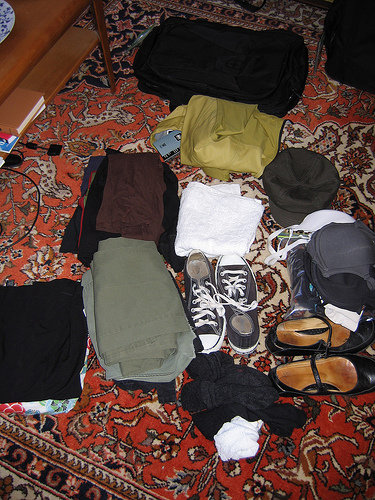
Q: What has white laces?
A: Sneakers.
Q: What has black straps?
A: Shoes.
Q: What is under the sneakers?
A: Rug.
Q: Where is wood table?
A: Left side.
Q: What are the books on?
A: Table shelf.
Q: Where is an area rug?
A: On the floor.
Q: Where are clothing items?
A: On the rug.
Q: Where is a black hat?
A: On the rug.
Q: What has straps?
A: Black shoes.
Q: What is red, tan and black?
A: The rug.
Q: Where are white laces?
A: On black and white sneakers.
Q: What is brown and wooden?
A: The floor.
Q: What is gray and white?
A: Sneakers.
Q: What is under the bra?
A: Mary janes.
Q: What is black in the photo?
A: Luggage.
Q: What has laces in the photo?
A: Shoes.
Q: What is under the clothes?
A: A rug.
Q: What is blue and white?
A: The sneakers.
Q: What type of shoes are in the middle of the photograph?
A: Sneakers.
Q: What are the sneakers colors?
A: Black and white?.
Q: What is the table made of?
A: Wood.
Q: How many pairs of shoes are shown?
A: Two.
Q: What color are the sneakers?
A: Navy.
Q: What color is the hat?
A: Black.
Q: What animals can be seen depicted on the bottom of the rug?
A: Deer.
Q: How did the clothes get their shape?
A: They were folded.